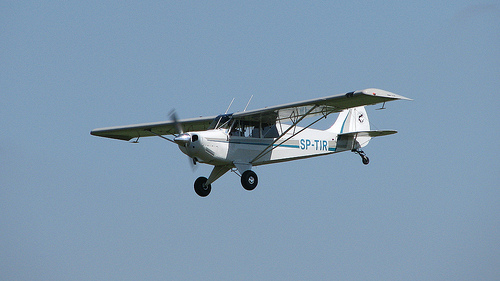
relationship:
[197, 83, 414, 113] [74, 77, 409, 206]
wing on a airplane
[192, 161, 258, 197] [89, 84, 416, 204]
gear on an airplane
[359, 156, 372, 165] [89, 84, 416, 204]
tail wheel of an airplane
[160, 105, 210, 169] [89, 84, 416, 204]
propeller of an airplane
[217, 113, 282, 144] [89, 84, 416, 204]
cockpit of an airplane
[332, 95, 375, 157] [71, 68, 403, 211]
rudder of airplane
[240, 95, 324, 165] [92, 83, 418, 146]
pole holding up wing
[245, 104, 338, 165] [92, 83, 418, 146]
pole holding up wing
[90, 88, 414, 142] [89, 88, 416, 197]
wing across top of airplane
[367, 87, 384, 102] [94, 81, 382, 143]
light on wing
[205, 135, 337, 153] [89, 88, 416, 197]
stripe down side of airplane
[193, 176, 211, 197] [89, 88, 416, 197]
front wheels on airplane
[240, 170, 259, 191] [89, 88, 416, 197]
tire on airplane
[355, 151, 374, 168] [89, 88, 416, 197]
wheel on airplane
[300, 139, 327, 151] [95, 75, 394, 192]
sp-tir on an airplane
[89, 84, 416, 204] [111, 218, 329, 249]
airplane airplane preparing for landing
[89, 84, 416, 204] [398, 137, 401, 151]
airplane above ground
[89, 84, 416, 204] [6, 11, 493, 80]
airplane flying in sky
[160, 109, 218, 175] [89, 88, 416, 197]
propeller on airplane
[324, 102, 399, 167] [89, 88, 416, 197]
tail on airplane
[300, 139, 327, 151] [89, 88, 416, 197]
sp-tir on airplane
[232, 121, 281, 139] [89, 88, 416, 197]
windows on airplane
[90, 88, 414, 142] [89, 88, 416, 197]
wing on airplane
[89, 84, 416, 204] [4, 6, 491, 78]
airplane in sky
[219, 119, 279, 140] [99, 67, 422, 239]
windows on airplane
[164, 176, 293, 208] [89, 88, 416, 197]
front wheels on airplane